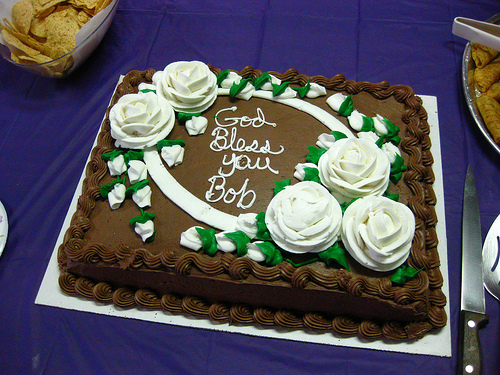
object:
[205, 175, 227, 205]
letters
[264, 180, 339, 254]
rose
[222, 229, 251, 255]
leaves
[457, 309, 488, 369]
handle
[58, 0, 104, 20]
chips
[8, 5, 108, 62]
paper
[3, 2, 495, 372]
cloth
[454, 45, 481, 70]
tongs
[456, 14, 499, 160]
pan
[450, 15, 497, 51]
handle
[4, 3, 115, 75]
bowl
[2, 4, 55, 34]
chips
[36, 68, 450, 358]
cardboard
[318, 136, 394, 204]
flowers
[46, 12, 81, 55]
chips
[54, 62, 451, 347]
icing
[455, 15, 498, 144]
food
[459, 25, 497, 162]
tin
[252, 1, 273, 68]
creases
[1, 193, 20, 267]
edge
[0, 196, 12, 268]
plate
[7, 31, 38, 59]
chips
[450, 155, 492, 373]
knife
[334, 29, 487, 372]
right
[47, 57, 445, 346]
cake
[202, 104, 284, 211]
writing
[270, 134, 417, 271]
group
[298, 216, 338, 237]
petals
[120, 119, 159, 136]
petals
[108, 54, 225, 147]
group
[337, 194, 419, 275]
flowers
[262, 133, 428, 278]
frosting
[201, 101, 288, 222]
writing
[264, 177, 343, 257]
flowers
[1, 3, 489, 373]
table